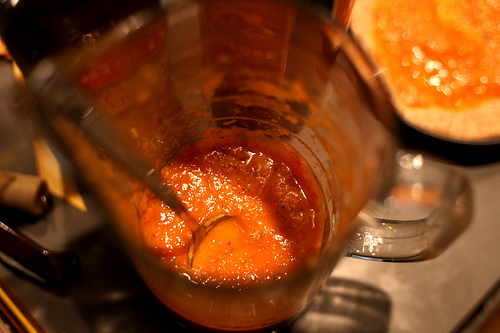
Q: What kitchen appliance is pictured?
A: Blender.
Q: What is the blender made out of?
A: Glass.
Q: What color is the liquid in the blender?
A: Orange.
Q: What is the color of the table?
A: Silver.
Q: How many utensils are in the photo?
A: One.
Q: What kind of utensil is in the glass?
A: Spoon.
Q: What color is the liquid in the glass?
A: Orange.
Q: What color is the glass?
A: Clear.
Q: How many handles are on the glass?
A: One.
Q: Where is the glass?
A: On grey countertop.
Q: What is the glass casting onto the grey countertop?
A: Shadow.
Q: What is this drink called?
A: Smoothie.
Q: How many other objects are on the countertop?
A: Three.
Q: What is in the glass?
A: Orange liquid.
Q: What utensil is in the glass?
A: Spoon.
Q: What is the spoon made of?
A: Metal.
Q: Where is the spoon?
A: In the orange liquid.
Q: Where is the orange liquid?
A: Bottom of the glass.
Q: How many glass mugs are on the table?
A: One.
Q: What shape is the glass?
A: Round.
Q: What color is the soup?
A: Orange.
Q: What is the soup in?
A: Container.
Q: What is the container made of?
A: Glass.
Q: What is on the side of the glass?
A: Handle.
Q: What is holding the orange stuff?
A: Glass.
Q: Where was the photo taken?
A: Inside somewhere.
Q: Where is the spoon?
A: In the glass.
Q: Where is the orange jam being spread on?
A: On a slice of bread roll.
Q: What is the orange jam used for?
A: The orange jam is used to spread on bread.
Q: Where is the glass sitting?
A: The glass is on a countertop.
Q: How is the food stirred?
A: A spoon.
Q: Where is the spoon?
A: In the cup.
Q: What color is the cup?
A: Clear.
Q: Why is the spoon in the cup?
A: To stir.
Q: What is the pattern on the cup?
A: Stripes.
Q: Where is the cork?
A: Behind the cup.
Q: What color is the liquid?
A: Orange.